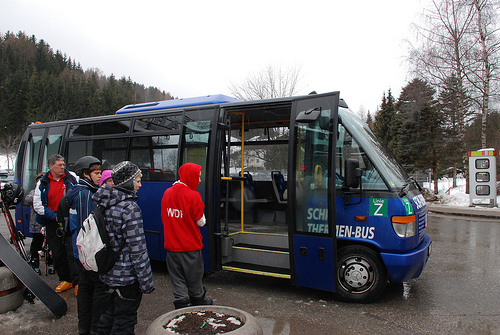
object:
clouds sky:
[83, 6, 93, 9]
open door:
[206, 90, 341, 295]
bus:
[10, 88, 436, 304]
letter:
[354, 226, 362, 238]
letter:
[361, 226, 369, 239]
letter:
[367, 227, 375, 240]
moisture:
[434, 215, 498, 334]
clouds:
[370, 13, 387, 23]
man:
[160, 161, 214, 310]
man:
[56, 155, 104, 335]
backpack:
[74, 196, 140, 275]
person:
[74, 159, 160, 333]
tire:
[333, 244, 389, 305]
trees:
[470, 0, 500, 147]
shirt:
[44, 171, 69, 213]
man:
[31, 153, 82, 298]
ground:
[0, 173, 500, 335]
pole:
[241, 113, 245, 231]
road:
[0, 185, 500, 334]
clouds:
[315, 17, 328, 24]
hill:
[0, 27, 184, 157]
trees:
[0, 27, 43, 179]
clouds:
[100, 0, 118, 8]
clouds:
[81, 25, 97, 35]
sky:
[0, 0, 500, 127]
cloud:
[135, 39, 172, 54]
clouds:
[342, 62, 355, 71]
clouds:
[284, 17, 291, 25]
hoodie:
[160, 161, 207, 252]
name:
[306, 207, 328, 220]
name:
[306, 223, 376, 240]